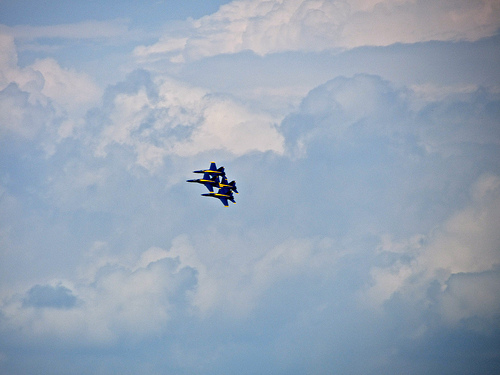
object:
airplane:
[209, 174, 238, 193]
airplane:
[185, 172, 219, 193]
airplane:
[200, 186, 237, 207]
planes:
[192, 161, 226, 179]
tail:
[228, 180, 239, 195]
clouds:
[156, 1, 397, 116]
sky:
[58, 4, 405, 156]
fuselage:
[213, 192, 235, 200]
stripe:
[213, 193, 231, 198]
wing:
[214, 197, 229, 208]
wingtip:
[222, 204, 230, 208]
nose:
[185, 179, 192, 183]